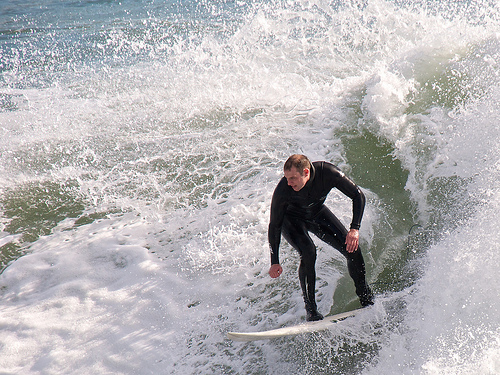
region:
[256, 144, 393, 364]
man surfing in the ocean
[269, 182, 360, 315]
black wet suit on man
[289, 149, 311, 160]
bald spot on man's head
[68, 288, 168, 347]
white foam in green water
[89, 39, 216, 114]
water spraying up in the air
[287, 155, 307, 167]
wet hair on man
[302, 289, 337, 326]
boot on bottom of man's foot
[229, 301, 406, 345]
white board under surfer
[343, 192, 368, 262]
man's hand on his knee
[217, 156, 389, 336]
Man in wetsuit on surfboard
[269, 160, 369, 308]
Black wetsuit on man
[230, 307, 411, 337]
White surfboard in waves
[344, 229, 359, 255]
Man's hand on knee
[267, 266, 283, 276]
Man's hand with cupped fingers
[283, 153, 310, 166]
Short brown hair on man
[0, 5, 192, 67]
Splashes of water from wave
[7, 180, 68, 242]
Green churning water in wave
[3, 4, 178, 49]
Gray ocean behind wave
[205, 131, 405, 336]
the man in the ocean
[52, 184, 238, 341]
the ocean is foaming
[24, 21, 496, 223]
the ocean is turbulent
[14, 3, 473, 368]
the ocean is opaque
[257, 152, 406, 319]
the man wearing wet suit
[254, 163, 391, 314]
the man is wet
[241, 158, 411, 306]
the wet suit is black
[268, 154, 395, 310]
the man on the surfboard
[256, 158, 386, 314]
the man is surfing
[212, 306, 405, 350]
the surfboard is white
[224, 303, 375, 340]
a white surfboard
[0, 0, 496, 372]
white water around a surfer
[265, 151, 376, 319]
a surfer on the water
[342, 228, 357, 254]
a surfer's hand resting on his knee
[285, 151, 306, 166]
a balding spot on a surfer's head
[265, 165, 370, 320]
a black wetsuit on a surfer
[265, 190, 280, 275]
the arm of a surfer hanging down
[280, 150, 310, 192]
the exposed head of a surfer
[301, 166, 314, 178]
the ear of a surfer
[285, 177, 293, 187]
the nose of a surfer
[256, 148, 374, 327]
a man in a black wet suite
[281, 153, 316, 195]
the head of a man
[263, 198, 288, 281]
the arm of a man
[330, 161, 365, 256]
the arm of a man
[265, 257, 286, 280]
the hand of a man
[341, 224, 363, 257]
the hand of a man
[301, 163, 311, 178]
the ear of a man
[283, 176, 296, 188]
the nose of a man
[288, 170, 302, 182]
the eye of a man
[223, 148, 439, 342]
a man surfing on a white surfboard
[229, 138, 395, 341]
man in black wetsuit on white surfboard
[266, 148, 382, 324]
man wearing black wetsuit on white board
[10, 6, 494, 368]
white splashing waves in ocean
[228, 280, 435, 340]
white surfboard coming out of waves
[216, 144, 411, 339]
man standing on white surfboard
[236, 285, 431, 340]
white surfboard in ocean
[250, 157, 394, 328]
black wetsuit on man surfing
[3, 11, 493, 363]
white foamy ocean waves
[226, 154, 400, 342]
man crouching on surfboard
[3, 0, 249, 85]
clear blue water in corner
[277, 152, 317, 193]
short blond hair on man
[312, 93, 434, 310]
green funnel of water behind surfboard